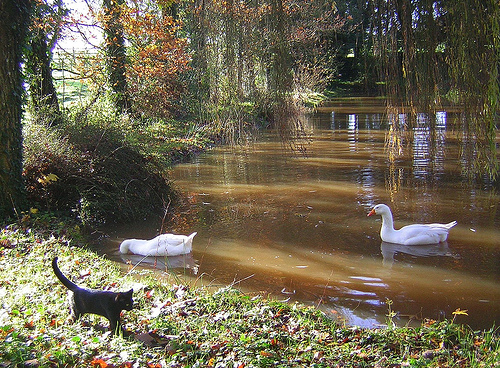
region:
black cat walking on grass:
[53, 277, 138, 324]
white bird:
[124, 229, 204, 266]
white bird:
[349, 200, 470, 260]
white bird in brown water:
[363, 199, 470, 250]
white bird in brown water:
[113, 236, 201, 257]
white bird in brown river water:
[361, 192, 461, 260]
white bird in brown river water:
[111, 225, 205, 270]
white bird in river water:
[362, 188, 464, 256]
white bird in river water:
[101, 215, 208, 268]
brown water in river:
[256, 220, 308, 268]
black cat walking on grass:
[33, 262, 154, 342]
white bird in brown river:
[355, 192, 457, 252]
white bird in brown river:
[116, 225, 206, 260]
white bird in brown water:
[110, 226, 208, 269]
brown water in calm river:
[264, 219, 308, 257]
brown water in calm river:
[260, 184, 311, 219]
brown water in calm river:
[421, 121, 490, 210]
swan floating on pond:
[364, 197, 462, 259]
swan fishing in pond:
[110, 220, 221, 271]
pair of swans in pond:
[90, 190, 476, 280]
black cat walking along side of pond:
[37, 238, 222, 363]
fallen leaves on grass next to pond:
[5, 212, 82, 288]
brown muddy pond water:
[322, 270, 455, 321]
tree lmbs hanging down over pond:
[210, 5, 495, 155]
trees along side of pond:
[12, 5, 339, 181]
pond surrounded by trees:
[42, 50, 488, 333]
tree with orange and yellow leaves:
[23, 0, 222, 161]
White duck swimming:
[367, 197, 458, 249]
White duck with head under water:
[116, 227, 202, 260]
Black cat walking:
[46, 246, 141, 336]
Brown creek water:
[281, 106, 367, 276]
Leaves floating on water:
[180, 183, 278, 226]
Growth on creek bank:
[63, 129, 165, 197]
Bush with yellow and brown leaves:
[59, 12, 190, 96]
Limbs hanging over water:
[371, 5, 498, 185]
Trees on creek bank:
[5, 11, 130, 196]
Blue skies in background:
[61, 4, 101, 49]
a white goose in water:
[113, 233, 198, 259]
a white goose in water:
[360, 197, 455, 247]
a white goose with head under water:
[116, 231, 197, 258]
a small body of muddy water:
[91, 89, 496, 331]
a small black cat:
[44, 255, 135, 333]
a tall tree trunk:
[0, 5, 30, 215]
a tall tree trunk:
[105, 0, 123, 110]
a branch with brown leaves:
[28, 3, 188, 91]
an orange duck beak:
[365, 208, 375, 218]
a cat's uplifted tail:
[46, 254, 71, 289]